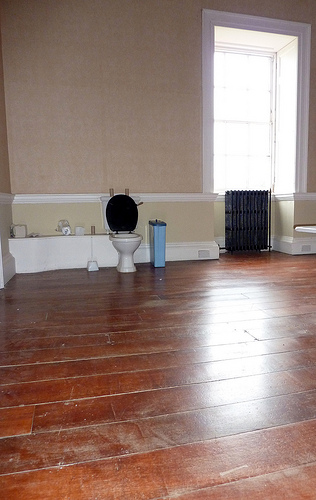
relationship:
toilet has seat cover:
[100, 195, 143, 274] [106, 195, 140, 233]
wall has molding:
[0, 1, 316, 259] [2, 192, 316, 207]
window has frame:
[214, 40, 278, 195] [199, 8, 313, 195]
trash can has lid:
[147, 220, 168, 268] [149, 218, 169, 228]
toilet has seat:
[100, 195, 143, 274] [108, 233, 144, 243]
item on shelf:
[12, 223, 28, 239] [7, 234, 112, 274]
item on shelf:
[28, 230, 40, 237] [7, 234, 112, 274]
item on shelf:
[60, 225, 72, 235] [7, 234, 112, 274]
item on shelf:
[74, 225, 89, 237] [7, 234, 112, 274]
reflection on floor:
[200, 275, 273, 426] [0, 250, 315, 498]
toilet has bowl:
[100, 195, 143, 274] [110, 232, 144, 255]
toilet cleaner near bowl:
[86, 233, 100, 272] [110, 232, 144, 255]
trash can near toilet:
[147, 220, 168, 268] [100, 195, 143, 274]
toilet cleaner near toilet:
[86, 233, 100, 272] [100, 195, 143, 274]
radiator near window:
[223, 188, 272, 251] [214, 40, 278, 195]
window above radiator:
[214, 40, 278, 195] [223, 188, 272, 251]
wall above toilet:
[0, 1, 316, 259] [100, 195, 143, 274]